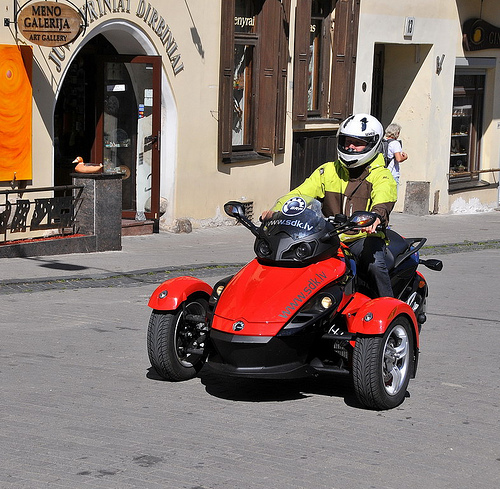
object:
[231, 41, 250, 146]
window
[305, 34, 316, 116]
window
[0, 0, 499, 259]
building